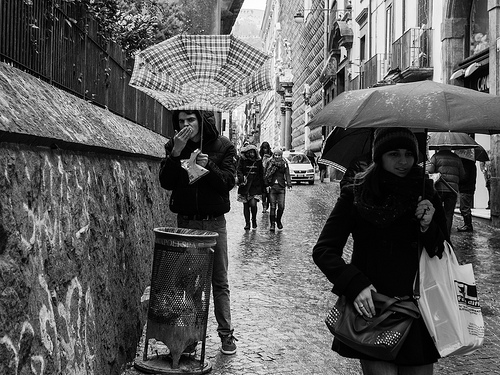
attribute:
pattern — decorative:
[370, 324, 412, 353]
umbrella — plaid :
[121, 29, 283, 121]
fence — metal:
[20, 27, 119, 95]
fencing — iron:
[0, 4, 172, 134]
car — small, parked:
[280, 150, 315, 187]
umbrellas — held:
[293, 76, 495, 148]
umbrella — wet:
[275, 70, 498, 132]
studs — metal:
[370, 329, 404, 349]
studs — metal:
[327, 304, 343, 330]